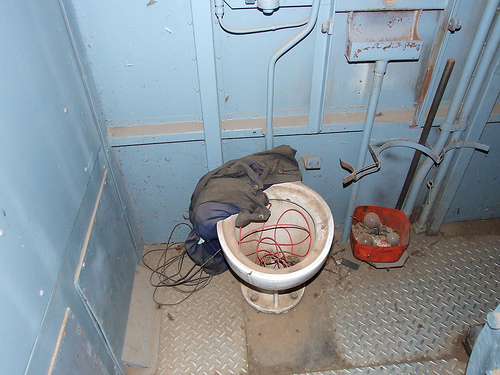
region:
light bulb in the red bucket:
[362, 212, 384, 229]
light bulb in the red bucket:
[383, 228, 400, 248]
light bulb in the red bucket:
[356, 230, 377, 247]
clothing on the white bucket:
[165, 143, 319, 230]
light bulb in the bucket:
[358, 212, 383, 229]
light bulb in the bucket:
[383, 228, 404, 245]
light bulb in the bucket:
[352, 233, 376, 246]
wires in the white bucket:
[242, 205, 310, 269]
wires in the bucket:
[237, 203, 312, 265]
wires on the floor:
[136, 218, 216, 310]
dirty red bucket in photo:
[344, 197, 427, 267]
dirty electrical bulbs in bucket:
[342, 170, 411, 249]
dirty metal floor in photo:
[180, 300, 307, 366]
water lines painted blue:
[222, 23, 324, 138]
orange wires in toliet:
[246, 217, 308, 258]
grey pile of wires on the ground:
[149, 233, 216, 293]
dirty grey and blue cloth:
[183, 158, 312, 203]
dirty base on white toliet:
[191, 160, 370, 325]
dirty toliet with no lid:
[193, 164, 370, 319]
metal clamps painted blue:
[342, 130, 420, 192]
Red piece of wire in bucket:
[234, 206, 317, 278]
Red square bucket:
[345, 190, 424, 275]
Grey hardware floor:
[117, 231, 497, 372]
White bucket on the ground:
[213, 173, 333, 323]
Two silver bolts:
[247, 290, 301, 309]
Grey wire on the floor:
[149, 226, 249, 318]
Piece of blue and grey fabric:
[177, 145, 315, 284]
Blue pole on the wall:
[339, 64, 391, 260]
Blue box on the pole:
[341, 9, 426, 71]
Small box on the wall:
[298, 147, 329, 181]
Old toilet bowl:
[220, 166, 341, 322]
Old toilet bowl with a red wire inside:
[212, 167, 334, 330]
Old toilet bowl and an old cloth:
[190, 144, 336, 310]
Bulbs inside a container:
[340, 199, 418, 275]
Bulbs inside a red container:
[346, 198, 417, 272]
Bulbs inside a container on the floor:
[345, 195, 422, 283]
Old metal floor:
[146, 325, 446, 373]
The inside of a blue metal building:
[24, 100, 138, 374]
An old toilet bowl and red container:
[213, 173, 421, 318]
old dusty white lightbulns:
[352, 213, 404, 245]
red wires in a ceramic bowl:
[242, 203, 314, 268]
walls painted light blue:
[45, 12, 449, 348]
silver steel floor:
[157, 243, 490, 374]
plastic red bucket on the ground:
[340, 192, 415, 267]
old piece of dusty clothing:
[187, 145, 304, 270]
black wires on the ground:
[129, 218, 235, 316]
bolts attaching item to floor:
[242, 288, 304, 308]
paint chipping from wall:
[349, 39, 426, 63]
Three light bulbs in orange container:
[347, 203, 412, 263]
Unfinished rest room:
[1, 2, 498, 374]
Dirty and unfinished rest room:
[2, 3, 498, 370]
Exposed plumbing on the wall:
[68, 0, 499, 244]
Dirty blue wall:
[0, 1, 499, 373]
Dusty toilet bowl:
[213, 178, 335, 315]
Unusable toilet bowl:
[214, 171, 336, 315]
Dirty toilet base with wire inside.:
[215, 178, 334, 314]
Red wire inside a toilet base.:
[237, 201, 312, 268]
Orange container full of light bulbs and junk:
[351, 203, 412, 264]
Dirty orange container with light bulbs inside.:
[348, 204, 413, 260]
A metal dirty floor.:
[156, 222, 499, 374]